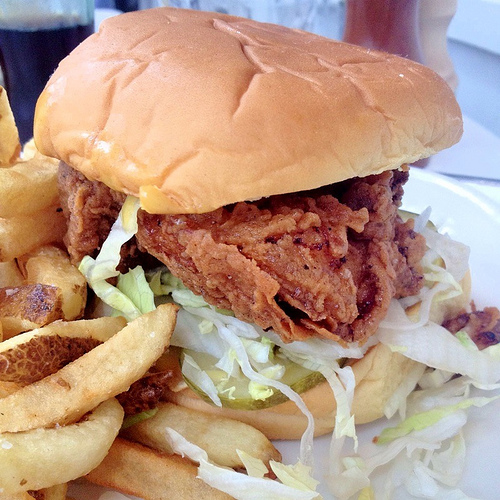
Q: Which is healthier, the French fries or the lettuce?
A: The lettuce is healthier than the French fries.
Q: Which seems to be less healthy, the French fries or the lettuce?
A: The French fries is less healthy than the lettuce.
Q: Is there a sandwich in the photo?
A: Yes, there is a sandwich.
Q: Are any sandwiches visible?
A: Yes, there is a sandwich.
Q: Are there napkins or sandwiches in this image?
A: Yes, there is a sandwich.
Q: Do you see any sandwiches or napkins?
A: Yes, there is a sandwich.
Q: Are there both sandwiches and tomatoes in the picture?
A: No, there is a sandwich but no tomatoes.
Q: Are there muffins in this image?
A: No, there are no muffins.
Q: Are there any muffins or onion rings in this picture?
A: No, there are no muffins or onion rings.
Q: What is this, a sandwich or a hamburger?
A: This is a sandwich.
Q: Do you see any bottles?
A: Yes, there is a bottle.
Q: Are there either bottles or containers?
A: Yes, there is a bottle.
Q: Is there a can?
A: No, there are no cans.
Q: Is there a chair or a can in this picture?
A: No, there are no cans or chairs.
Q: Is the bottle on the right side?
A: Yes, the bottle is on the right of the image.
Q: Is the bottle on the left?
A: No, the bottle is on the right of the image.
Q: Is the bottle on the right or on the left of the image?
A: The bottle is on the right of the image.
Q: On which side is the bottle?
A: The bottle is on the right of the image.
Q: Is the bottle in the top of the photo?
A: Yes, the bottle is in the top of the image.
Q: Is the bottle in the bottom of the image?
A: No, the bottle is in the top of the image.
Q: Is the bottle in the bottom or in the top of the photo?
A: The bottle is in the top of the image.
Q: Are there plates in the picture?
A: Yes, there is a plate.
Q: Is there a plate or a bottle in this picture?
A: Yes, there is a plate.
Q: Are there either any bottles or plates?
A: Yes, there is a plate.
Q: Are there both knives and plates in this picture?
A: No, there is a plate but no knives.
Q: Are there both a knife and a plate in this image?
A: No, there is a plate but no knives.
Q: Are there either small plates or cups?
A: Yes, there is a small plate.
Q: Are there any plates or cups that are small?
A: Yes, the plate is small.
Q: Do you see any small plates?
A: Yes, there is a small plate.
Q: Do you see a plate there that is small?
A: Yes, there is a plate that is small.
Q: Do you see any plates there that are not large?
A: Yes, there is a small plate.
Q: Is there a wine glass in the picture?
A: No, there are no wine glasses.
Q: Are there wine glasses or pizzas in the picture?
A: No, there are no wine glasses or pizzas.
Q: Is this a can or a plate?
A: This is a plate.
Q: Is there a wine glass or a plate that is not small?
A: No, there is a plate but it is small.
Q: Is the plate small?
A: Yes, the plate is small.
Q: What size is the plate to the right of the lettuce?
A: The plate is small.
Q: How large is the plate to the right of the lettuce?
A: The plate is small.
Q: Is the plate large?
A: No, the plate is small.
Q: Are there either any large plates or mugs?
A: No, there is a plate but it is small.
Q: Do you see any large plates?
A: No, there is a plate but it is small.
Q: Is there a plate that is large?
A: No, there is a plate but it is small.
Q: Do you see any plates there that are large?
A: No, there is a plate but it is small.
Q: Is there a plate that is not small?
A: No, there is a plate but it is small.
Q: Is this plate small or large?
A: The plate is small.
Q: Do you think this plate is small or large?
A: The plate is small.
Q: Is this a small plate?
A: Yes, this is a small plate.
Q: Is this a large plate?
A: No, this is a small plate.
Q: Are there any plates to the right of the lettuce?
A: Yes, there is a plate to the right of the lettuce.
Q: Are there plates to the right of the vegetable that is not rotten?
A: Yes, there is a plate to the right of the lettuce.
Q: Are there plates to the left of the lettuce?
A: No, the plate is to the right of the lettuce.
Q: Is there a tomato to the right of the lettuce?
A: No, there is a plate to the right of the lettuce.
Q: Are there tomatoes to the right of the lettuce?
A: No, there is a plate to the right of the lettuce.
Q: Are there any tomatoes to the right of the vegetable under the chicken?
A: No, there is a plate to the right of the lettuce.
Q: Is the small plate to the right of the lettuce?
A: Yes, the plate is to the right of the lettuce.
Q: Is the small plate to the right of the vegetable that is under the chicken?
A: Yes, the plate is to the right of the lettuce.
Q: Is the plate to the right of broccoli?
A: No, the plate is to the right of the lettuce.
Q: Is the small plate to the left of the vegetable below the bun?
A: No, the plate is to the right of the lettuce.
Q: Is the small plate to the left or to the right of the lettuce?
A: The plate is to the right of the lettuce.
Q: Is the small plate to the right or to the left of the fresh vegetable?
A: The plate is to the right of the lettuce.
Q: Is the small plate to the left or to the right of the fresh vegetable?
A: The plate is to the right of the lettuce.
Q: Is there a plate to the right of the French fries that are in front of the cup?
A: Yes, there is a plate to the right of the fries.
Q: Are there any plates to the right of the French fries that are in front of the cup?
A: Yes, there is a plate to the right of the fries.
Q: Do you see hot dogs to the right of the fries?
A: No, there is a plate to the right of the fries.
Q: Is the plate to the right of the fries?
A: Yes, the plate is to the right of the fries.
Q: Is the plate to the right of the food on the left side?
A: Yes, the plate is to the right of the fries.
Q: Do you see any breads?
A: Yes, there is a bread.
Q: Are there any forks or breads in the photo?
A: Yes, there is a bread.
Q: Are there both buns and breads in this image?
A: Yes, there are both a bread and a bun.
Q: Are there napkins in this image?
A: No, there are no napkins.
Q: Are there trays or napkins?
A: No, there are no napkins or trays.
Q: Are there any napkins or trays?
A: No, there are no napkins or trays.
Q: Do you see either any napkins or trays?
A: No, there are no napkins or trays.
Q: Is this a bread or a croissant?
A: This is a bread.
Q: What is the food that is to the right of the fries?
A: The food is a bread.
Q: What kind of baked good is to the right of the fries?
A: The food is a bread.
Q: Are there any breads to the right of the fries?
A: Yes, there is a bread to the right of the fries.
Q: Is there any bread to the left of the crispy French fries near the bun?
A: No, the bread is to the right of the fries.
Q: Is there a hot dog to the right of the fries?
A: No, there is a bread to the right of the fries.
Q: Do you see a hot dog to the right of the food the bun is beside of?
A: No, there is a bread to the right of the fries.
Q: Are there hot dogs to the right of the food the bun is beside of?
A: No, there is a bread to the right of the fries.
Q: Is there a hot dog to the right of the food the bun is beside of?
A: No, there is a bread to the right of the fries.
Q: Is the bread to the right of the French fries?
A: Yes, the bread is to the right of the French fries.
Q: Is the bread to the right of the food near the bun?
A: Yes, the bread is to the right of the French fries.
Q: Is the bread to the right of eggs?
A: No, the bread is to the right of the French fries.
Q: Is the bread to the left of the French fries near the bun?
A: No, the bread is to the right of the fries.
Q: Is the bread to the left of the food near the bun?
A: No, the bread is to the right of the fries.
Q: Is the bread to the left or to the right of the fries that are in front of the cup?
A: The bread is to the right of the fries.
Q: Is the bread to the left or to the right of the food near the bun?
A: The bread is to the right of the fries.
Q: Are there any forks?
A: No, there are no forks.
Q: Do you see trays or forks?
A: No, there are no forks or trays.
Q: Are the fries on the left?
A: Yes, the fries are on the left of the image.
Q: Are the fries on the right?
A: No, the fries are on the left of the image.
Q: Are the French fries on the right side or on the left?
A: The French fries are on the left of the image.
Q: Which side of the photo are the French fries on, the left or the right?
A: The French fries are on the left of the image.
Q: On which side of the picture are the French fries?
A: The French fries are on the left of the image.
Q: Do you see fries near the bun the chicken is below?
A: Yes, there are fries near the bun.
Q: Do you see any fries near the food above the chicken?
A: Yes, there are fries near the bun.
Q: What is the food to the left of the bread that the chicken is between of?
A: The food is fries.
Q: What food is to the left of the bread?
A: The food is fries.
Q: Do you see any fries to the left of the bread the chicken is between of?
A: Yes, there are fries to the left of the bread.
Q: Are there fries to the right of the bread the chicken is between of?
A: No, the fries are to the left of the bread.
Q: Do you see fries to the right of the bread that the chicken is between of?
A: No, the fries are to the left of the bread.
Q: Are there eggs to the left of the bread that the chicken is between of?
A: No, there are fries to the left of the bread.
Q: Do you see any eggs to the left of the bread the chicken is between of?
A: No, there are fries to the left of the bread.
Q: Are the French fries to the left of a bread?
A: Yes, the French fries are to the left of a bread.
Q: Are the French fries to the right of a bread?
A: No, the French fries are to the left of a bread.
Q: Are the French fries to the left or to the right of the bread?
A: The French fries are to the left of the bread.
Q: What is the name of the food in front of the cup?
A: The food is fries.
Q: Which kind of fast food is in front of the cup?
A: The food is fries.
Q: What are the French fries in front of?
A: The French fries are in front of the cup.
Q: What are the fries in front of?
A: The French fries are in front of the cup.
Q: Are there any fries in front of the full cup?
A: Yes, there are fries in front of the cup.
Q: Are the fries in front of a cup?
A: Yes, the fries are in front of a cup.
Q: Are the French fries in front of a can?
A: No, the French fries are in front of a cup.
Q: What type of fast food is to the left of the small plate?
A: The food is fries.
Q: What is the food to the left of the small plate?
A: The food is fries.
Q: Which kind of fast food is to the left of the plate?
A: The food is fries.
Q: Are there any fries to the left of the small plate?
A: Yes, there are fries to the left of the plate.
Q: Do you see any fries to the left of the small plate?
A: Yes, there are fries to the left of the plate.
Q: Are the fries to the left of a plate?
A: Yes, the fries are to the left of a plate.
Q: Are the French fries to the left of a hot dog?
A: No, the French fries are to the left of a plate.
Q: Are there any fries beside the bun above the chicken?
A: Yes, there are fries beside the bun.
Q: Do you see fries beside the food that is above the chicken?
A: Yes, there are fries beside the bun.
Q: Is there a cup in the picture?
A: Yes, there is a cup.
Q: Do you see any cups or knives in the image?
A: Yes, there is a cup.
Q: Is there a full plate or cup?
A: Yes, there is a full cup.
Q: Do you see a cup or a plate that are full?
A: Yes, the cup is full.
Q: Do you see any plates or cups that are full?
A: Yes, the cup is full.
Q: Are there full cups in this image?
A: Yes, there is a full cup.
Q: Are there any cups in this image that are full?
A: Yes, there is a cup that is full.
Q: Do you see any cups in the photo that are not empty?
A: Yes, there is an full cup.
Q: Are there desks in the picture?
A: No, there are no desks.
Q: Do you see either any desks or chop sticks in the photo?
A: No, there are no desks or chop sticks.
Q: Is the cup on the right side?
A: No, the cup is on the left of the image.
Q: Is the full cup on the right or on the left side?
A: The cup is on the left of the image.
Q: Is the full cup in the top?
A: Yes, the cup is in the top of the image.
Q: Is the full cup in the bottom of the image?
A: No, the cup is in the top of the image.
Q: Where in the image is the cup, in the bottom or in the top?
A: The cup is in the top of the image.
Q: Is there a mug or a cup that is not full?
A: No, there is a cup but it is full.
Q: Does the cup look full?
A: Yes, the cup is full.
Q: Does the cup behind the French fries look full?
A: Yes, the cup is full.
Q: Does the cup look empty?
A: No, the cup is full.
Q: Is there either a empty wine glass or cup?
A: No, there is a cup but it is full.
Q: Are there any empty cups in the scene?
A: No, there is a cup but it is full.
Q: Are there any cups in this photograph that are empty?
A: No, there is a cup but it is full.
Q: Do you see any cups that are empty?
A: No, there is a cup but it is full.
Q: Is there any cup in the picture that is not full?
A: No, there is a cup but it is full.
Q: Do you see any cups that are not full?
A: No, there is a cup but it is full.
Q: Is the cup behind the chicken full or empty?
A: The cup is full.